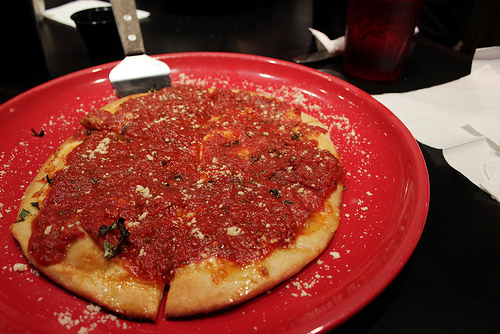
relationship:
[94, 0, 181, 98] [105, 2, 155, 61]
pizza spatula has handle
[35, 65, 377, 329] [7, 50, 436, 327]
pizza sitting on plate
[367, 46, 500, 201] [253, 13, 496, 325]
napkin sitting on table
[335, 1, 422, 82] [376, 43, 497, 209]
plastic cup sitting next to napkin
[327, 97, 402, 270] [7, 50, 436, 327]
parmesan on plate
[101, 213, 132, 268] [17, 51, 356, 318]
basil on pizza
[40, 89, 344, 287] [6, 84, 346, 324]
marinara sauce covering pizza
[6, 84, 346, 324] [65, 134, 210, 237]
pizza has spices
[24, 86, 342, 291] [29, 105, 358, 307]
tomato paste on pizza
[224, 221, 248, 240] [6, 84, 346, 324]
cheese on pizza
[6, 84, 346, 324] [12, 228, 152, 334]
pizza has crust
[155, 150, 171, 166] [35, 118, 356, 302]
seasoning on pizza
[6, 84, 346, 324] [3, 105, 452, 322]
pizza on plate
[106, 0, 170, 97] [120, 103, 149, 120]
pizza spatula has handle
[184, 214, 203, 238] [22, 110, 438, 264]
cheese on plate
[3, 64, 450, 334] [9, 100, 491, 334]
plate on surface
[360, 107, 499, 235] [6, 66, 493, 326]
napkin on surface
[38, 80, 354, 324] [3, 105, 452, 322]
pie on plate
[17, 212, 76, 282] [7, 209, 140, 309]
tomatoes on crust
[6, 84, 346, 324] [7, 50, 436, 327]
pizza on plate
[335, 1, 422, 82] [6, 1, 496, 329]
plastic cup on table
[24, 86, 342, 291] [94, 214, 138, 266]
tomato paste with herb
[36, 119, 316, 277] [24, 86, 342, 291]
parmesan cheese on tomato paste